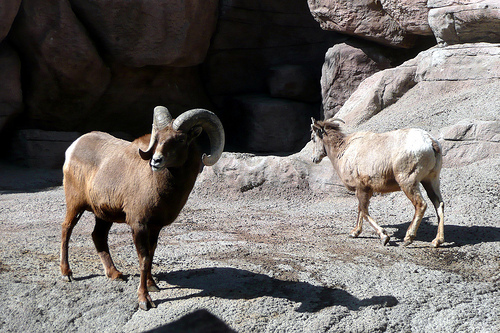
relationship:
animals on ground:
[62, 104, 448, 311] [0, 166, 498, 332]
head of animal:
[308, 117, 339, 162] [310, 117, 450, 251]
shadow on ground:
[154, 266, 397, 314] [0, 166, 498, 332]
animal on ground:
[310, 117, 450, 251] [0, 166, 498, 332]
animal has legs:
[310, 117, 450, 251] [347, 185, 445, 250]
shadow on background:
[233, 23, 288, 91] [0, 1, 498, 216]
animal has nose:
[310, 117, 450, 251] [310, 154, 318, 163]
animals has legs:
[57, 104, 227, 310] [61, 205, 160, 313]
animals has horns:
[57, 104, 227, 310] [139, 105, 226, 167]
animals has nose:
[57, 104, 227, 310] [150, 149, 163, 164]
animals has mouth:
[57, 104, 227, 310] [150, 159, 164, 172]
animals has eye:
[57, 104, 227, 310] [169, 136, 182, 149]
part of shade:
[17, 155, 36, 173] [3, 64, 59, 193]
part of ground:
[39, 295, 60, 308] [0, 166, 498, 332]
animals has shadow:
[57, 104, 227, 310] [154, 266, 397, 314]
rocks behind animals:
[267, 7, 498, 167] [57, 104, 227, 310]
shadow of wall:
[233, 23, 288, 91] [1, 1, 498, 157]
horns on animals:
[139, 105, 226, 167] [57, 104, 227, 310]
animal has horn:
[310, 117, 450, 251] [326, 114, 347, 126]